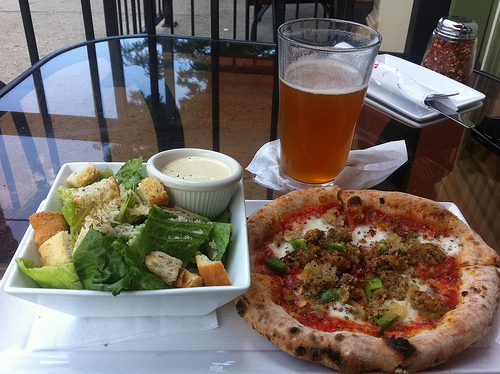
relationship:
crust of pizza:
[264, 334, 480, 373] [239, 185, 499, 370]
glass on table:
[277, 18, 380, 186] [0, 33, 499, 371]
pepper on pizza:
[365, 277, 383, 299] [239, 185, 499, 370]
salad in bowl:
[23, 161, 234, 290] [2, 161, 249, 317]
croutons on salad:
[68, 167, 126, 227] [23, 161, 234, 290]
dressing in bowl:
[161, 157, 228, 179] [144, 148, 241, 216]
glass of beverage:
[277, 18, 380, 186] [279, 64, 365, 180]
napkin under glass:
[246, 138, 408, 190] [277, 18, 380, 186]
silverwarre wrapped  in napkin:
[429, 95, 477, 129] [334, 41, 443, 104]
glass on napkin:
[277, 18, 380, 186] [246, 138, 408, 190]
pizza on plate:
[239, 185, 499, 370] [2, 199, 499, 372]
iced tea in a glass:
[279, 64, 365, 180] [277, 18, 380, 186]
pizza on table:
[239, 185, 499, 370] [0, 33, 499, 371]